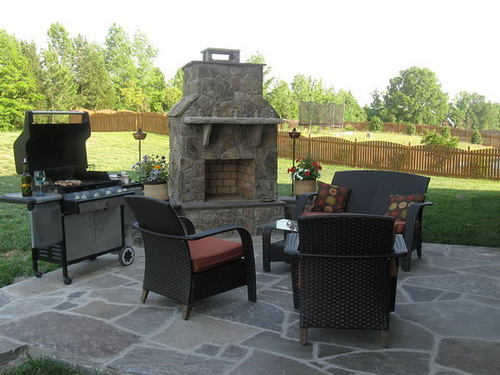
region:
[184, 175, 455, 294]
a patio set outside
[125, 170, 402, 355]
outside chairs with cushions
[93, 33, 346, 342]
an outside fireplace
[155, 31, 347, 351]
a fireplace that is outside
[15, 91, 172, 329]
a barbque grill outside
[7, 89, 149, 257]
a barbque grill with food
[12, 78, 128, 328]
a barbque grill with wheels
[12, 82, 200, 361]
a barbque grill with lid up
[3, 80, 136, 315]
a barbque girl with lid open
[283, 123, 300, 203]
A tall light near the porch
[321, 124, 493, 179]
A brown fence lining the yard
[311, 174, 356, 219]
A pillow with round designs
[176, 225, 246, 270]
Dark red cushion of a patio chair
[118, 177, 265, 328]
A black patio chair on the patio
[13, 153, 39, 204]
A bottle of liquid seasoning on he pit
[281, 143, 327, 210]
A green and red plant in the yard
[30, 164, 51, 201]
A wine glass sitting on the pit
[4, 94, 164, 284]
A large barbeque on the patio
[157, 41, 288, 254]
stone fireplace sitting outside on patio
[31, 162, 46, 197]
wine glass sitting on grill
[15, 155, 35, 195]
bottle sitting on grill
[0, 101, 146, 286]
grill sitting outside on patio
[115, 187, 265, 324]
brown chair sitting outside on patio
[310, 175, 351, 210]
throw pillow sitting on settee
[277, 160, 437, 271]
settee sitting outside on patio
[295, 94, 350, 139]
trampoline outside in backyard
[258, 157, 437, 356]
outdoor furniture sitting on patio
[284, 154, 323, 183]
red and white flowers inside of flower pot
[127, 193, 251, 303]
this is a chair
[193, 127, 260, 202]
this is the fire place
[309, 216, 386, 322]
the sofa is black in color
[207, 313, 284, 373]
this is the floor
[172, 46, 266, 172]
the chimney is short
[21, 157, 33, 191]
this is a bottle of wine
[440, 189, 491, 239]
these are the grass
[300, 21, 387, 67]
this is the sky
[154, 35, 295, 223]
the chimenia on the patio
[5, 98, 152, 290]
the gas grill on the patio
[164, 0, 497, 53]
the sky is clear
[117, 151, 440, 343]
the patio furniture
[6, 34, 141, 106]
trees with green leaves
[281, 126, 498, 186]
the fence of the yard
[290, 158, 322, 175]
red flowers in the pot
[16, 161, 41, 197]
the bottle on the grill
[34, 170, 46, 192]
the glass beside the bottle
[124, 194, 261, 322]
the large black wicker chair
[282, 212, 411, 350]
the large black wicker chair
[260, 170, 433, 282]
the large black wicker chair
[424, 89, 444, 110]
green leaves on the tree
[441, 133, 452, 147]
green leaves on the tree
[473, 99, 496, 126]
green leaves on the tree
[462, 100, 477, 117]
green leaves on the tree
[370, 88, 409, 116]
green leaves on the tree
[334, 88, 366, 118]
green leaves on the tree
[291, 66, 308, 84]
green leaves on the tree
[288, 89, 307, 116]
green leaves on the tree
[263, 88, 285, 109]
green leaves on the tree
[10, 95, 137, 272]
a outdoor grill with wheels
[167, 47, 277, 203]
a outdoor fire place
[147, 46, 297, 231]
a outdoor fireplace made of rocks